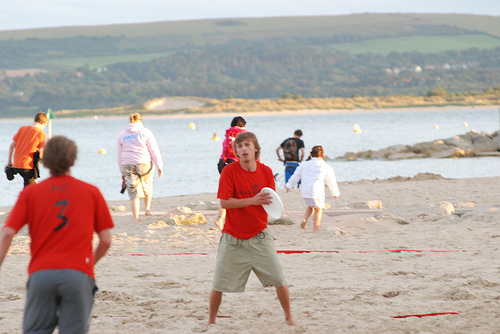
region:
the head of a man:
[222, 105, 290, 177]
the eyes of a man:
[225, 135, 252, 157]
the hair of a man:
[224, 105, 299, 158]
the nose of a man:
[226, 140, 278, 169]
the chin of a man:
[228, 143, 273, 183]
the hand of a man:
[242, 185, 281, 217]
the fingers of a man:
[239, 180, 290, 215]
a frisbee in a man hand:
[243, 185, 285, 227]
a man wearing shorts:
[200, 231, 317, 294]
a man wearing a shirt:
[204, 145, 311, 247]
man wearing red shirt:
[214, 159, 286, 241]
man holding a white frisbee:
[255, 178, 292, 222]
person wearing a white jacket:
[289, 156, 337, 202]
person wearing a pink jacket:
[110, 124, 167, 165]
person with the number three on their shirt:
[42, 192, 73, 232]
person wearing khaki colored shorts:
[198, 223, 297, 293]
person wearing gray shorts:
[20, 263, 86, 328]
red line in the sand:
[293, 242, 478, 272]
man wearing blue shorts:
[278, 155, 303, 190]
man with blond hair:
[226, 125, 261, 159]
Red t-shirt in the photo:
[221, 164, 277, 237]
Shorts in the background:
[212, 228, 282, 293]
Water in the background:
[331, 109, 383, 144]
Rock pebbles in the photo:
[362, 187, 479, 222]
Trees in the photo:
[213, 44, 290, 86]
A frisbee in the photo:
[251, 181, 296, 224]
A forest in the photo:
[151, 56, 248, 86]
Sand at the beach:
[341, 261, 397, 297]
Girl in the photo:
[284, 141, 341, 236]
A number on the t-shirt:
[45, 189, 82, 244]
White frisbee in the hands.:
[257, 184, 286, 226]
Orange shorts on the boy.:
[208, 128, 285, 247]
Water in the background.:
[0, 112, 495, 205]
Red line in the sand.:
[385, 305, 457, 323]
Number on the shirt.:
[45, 191, 70, 238]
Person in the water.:
[205, 130, 220, 143]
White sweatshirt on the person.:
[112, 107, 164, 179]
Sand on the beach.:
[2, 174, 498, 332]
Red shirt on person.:
[216, 114, 253, 161]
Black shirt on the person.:
[275, 125, 309, 164]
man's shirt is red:
[213, 155, 284, 242]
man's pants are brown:
[208, 221, 294, 296]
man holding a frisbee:
[201, 133, 309, 328]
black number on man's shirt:
[49, 191, 69, 236]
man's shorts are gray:
[12, 258, 107, 331]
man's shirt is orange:
[6, 123, 46, 174]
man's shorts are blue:
[275, 155, 306, 184]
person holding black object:
[1, 111, 60, 185]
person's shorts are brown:
[116, 147, 166, 197]